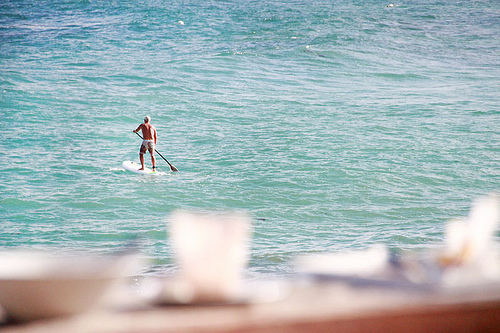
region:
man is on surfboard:
[127, 102, 181, 194]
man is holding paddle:
[138, 124, 195, 189]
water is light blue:
[245, 59, 365, 189]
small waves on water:
[242, 81, 290, 173]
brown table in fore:
[73, 221, 497, 311]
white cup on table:
[170, 207, 271, 310]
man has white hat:
[131, 107, 171, 131]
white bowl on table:
[10, 229, 107, 309]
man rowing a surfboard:
[123, 107, 179, 180]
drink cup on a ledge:
[159, 191, 268, 307]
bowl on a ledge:
[5, 226, 125, 323]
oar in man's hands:
[155, 144, 187, 179]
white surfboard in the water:
[123, 155, 168, 189]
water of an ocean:
[264, 65, 428, 199]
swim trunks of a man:
[138, 132, 156, 154]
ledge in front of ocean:
[10, 257, 497, 324]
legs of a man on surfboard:
[137, 151, 156, 173]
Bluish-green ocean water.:
[2, 1, 494, 233]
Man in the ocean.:
[118, 115, 180, 177]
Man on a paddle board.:
[118, 112, 183, 179]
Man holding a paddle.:
[129, 113, 181, 175]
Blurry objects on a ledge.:
[3, 198, 495, 327]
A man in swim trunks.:
[125, 115, 181, 178]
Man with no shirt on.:
[116, 115, 181, 180]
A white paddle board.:
[122, 156, 165, 180]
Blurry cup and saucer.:
[144, 207, 286, 310]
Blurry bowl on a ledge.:
[3, 242, 145, 318]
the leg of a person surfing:
[135, 143, 146, 172]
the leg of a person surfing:
[147, 146, 156, 176]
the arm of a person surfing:
[130, 121, 141, 134]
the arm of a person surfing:
[153, 126, 156, 143]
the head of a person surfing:
[142, 115, 150, 123]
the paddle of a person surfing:
[132, 128, 178, 176]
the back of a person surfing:
[140, 122, 155, 139]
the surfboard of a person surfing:
[122, 160, 166, 182]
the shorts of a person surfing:
[139, 138, 154, 152]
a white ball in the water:
[387, 3, 396, 10]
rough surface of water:
[4, 1, 496, 245]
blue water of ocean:
[4, 1, 496, 249]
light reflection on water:
[3, 2, 498, 265]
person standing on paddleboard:
[124, 116, 175, 174]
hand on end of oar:
[132, 128, 178, 171]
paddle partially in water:
[135, 131, 183, 172]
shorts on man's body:
[140, 136, 155, 156]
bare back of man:
[135, 123, 157, 138]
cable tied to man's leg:
[138, 153, 160, 172]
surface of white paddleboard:
[120, 159, 158, 176]